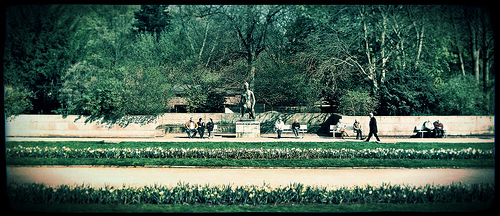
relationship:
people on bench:
[163, 113, 464, 143] [165, 114, 449, 144]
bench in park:
[165, 114, 449, 144] [13, 33, 484, 195]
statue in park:
[219, 79, 268, 123] [13, 33, 484, 195]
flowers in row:
[11, 139, 499, 160] [9, 138, 497, 209]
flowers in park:
[11, 139, 499, 160] [13, 33, 484, 195]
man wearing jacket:
[347, 109, 385, 151] [363, 114, 386, 131]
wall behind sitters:
[1, 111, 499, 149] [411, 116, 451, 144]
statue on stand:
[219, 79, 268, 123] [228, 119, 268, 143]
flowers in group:
[11, 139, 499, 160] [17, 145, 241, 205]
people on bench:
[184, 113, 444, 143] [204, 124, 447, 138]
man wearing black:
[364, 112, 381, 142] [362, 115, 387, 145]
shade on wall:
[97, 112, 162, 128] [1, 111, 499, 149]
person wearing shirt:
[270, 104, 285, 144] [271, 119, 284, 132]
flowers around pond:
[11, 139, 499, 160] [21, 162, 487, 193]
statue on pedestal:
[219, 79, 268, 123] [231, 115, 268, 156]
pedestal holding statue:
[231, 115, 268, 156] [219, 79, 268, 123]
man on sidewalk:
[347, 109, 385, 151] [11, 132, 498, 143]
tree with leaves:
[375, 59, 456, 115] [373, 60, 452, 119]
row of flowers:
[9, 138, 497, 209] [11, 139, 499, 160]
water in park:
[47, 168, 462, 192] [13, 33, 484, 195]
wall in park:
[1, 111, 499, 149] [13, 33, 484, 195]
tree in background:
[0, 5, 494, 115] [16, 39, 476, 136]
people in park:
[163, 113, 464, 143] [13, 33, 484, 195]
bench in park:
[204, 124, 447, 138] [13, 33, 484, 195]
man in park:
[347, 109, 385, 151] [13, 33, 484, 195]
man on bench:
[352, 117, 364, 141] [204, 124, 447, 138]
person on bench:
[270, 104, 285, 144] [271, 118, 312, 140]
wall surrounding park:
[1, 111, 499, 149] [13, 33, 484, 195]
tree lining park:
[0, 5, 494, 115] [13, 33, 484, 195]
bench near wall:
[204, 124, 447, 138] [1, 111, 499, 149]